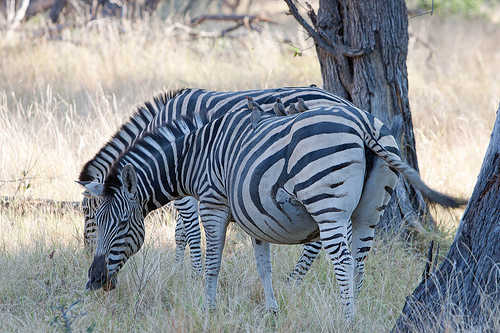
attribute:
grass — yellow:
[27, 41, 497, 144]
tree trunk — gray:
[385, 116, 495, 330]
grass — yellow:
[35, 261, 183, 328]